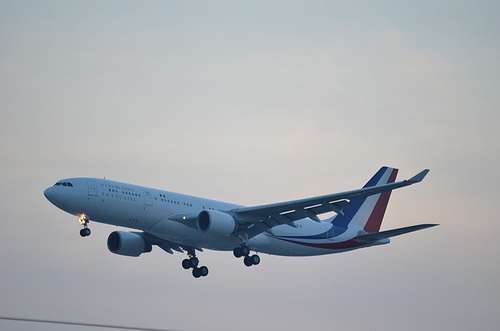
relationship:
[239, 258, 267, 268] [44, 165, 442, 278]
back wheel on airplane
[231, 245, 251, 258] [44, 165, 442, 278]
back wheel on airplane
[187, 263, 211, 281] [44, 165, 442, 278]
back wheel on airplane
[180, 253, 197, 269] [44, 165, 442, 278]
back wheel on airplane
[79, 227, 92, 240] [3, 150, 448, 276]
wheel on plane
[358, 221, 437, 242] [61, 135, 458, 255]
wing on plane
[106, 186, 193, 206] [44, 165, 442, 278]
windows on airplane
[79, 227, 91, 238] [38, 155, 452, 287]
wheel on airplane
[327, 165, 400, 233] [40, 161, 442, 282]
wing on back of airplane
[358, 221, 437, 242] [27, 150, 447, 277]
wing of airplane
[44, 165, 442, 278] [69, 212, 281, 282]
airplane deploying gear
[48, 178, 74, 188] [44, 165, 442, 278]
windshield of airplane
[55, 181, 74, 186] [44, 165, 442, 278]
window of airplane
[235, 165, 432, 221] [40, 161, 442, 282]
wing on airplane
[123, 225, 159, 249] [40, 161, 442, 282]
wing on airplane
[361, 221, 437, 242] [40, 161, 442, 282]
wing on airplane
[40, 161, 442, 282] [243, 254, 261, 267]
airplane has back wheel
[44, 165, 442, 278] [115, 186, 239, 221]
airplane has windows